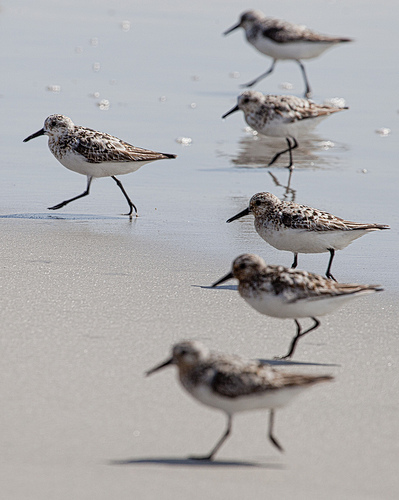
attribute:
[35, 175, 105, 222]
leg — bent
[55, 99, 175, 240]
bird — sandpiper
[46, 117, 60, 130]
black eye — Small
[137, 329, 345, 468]
sandpiper — blurry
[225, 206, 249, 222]
beak — long, black